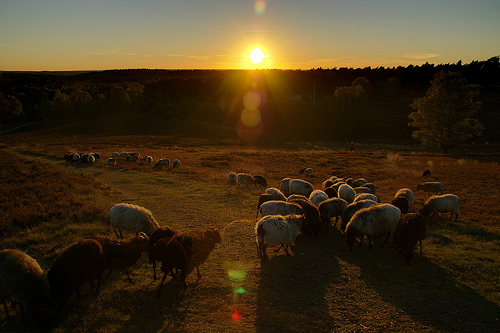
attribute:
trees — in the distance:
[214, 58, 484, 88]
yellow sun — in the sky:
[240, 40, 270, 74]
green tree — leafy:
[410, 69, 480, 162]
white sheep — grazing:
[106, 200, 166, 238]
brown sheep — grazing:
[141, 224, 229, 286]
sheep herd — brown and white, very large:
[15, 155, 465, 327]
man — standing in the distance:
[346, 138, 359, 154]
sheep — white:
[246, 215, 327, 250]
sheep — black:
[138, 226, 246, 282]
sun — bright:
[239, 45, 270, 75]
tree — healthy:
[421, 67, 472, 154]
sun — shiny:
[233, 40, 275, 76]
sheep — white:
[129, 165, 491, 324]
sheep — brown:
[40, 108, 486, 331]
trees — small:
[12, 65, 449, 148]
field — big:
[3, 132, 458, 303]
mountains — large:
[3, 60, 456, 155]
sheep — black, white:
[2, 184, 220, 315]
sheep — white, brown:
[249, 168, 431, 275]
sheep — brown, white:
[141, 219, 228, 293]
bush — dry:
[405, 149, 497, 200]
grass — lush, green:
[2, 134, 493, 328]